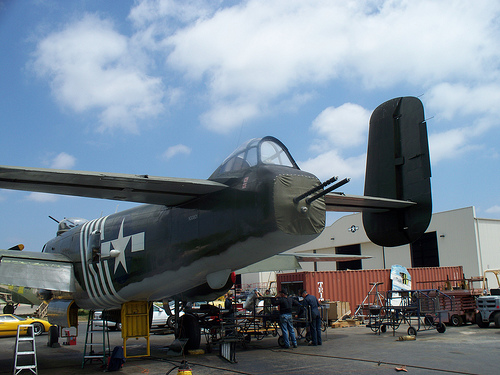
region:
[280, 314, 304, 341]
the pants are blue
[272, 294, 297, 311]
the shirt is black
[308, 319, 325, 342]
the pants are blue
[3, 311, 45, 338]
the car is yellow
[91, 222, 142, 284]
star is on the plane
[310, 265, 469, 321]
the container is red in color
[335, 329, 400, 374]
the ground is grey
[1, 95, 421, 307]
the plane is under repair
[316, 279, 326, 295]
letters are on the container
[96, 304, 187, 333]
the car is white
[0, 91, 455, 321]
large airplane being worked on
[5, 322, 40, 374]
small silver metal ladder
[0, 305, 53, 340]
yellow car parked near airplane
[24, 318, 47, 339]
black tire on yellow car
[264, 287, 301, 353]
person standing under the airplane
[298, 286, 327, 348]
person standing under the airplane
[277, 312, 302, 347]
pair of blue jeans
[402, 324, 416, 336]
black tire on a scaffolding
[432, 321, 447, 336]
black tire on a scaffolding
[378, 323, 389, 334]
black tire on a scaffolding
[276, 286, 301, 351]
one man wearing dark short sleeved shirt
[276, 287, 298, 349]
one man wearing blue jeans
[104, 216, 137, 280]
large white star on blue background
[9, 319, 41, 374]
one small shiny aluminum ladder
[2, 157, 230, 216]
one large gray airplane wing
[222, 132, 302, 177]
one domed airplane window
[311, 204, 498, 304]
one large white airplane hangar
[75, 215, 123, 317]
broad white stripes on side of airplane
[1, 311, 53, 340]
little yellow sunlit sports car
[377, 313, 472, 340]
several round black wheels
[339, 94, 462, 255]
mirror on the airplane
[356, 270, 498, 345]
forklift parked on the road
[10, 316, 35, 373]
metal ladder on the road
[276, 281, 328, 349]
two men working on the airplane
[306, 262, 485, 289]
red dumpster along a building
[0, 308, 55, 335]
yellow car parked on the road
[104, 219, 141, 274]
star on side of a plane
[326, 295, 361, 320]
cardboard boxes on the crate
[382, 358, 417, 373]
a cloth laying on the ground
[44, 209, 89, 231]
back propeller on the plane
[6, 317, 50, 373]
metal ladder on runway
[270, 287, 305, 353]
man in blue jeans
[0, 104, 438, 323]
fighter airplane on runway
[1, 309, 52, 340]
yellow sports car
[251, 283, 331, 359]
men on a runway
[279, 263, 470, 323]
red storage trailer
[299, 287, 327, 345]
man in a blue shirt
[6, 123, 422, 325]
large gray airplane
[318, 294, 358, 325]
cardboard boxes on the ground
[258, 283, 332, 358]
men performing airplane maintenance